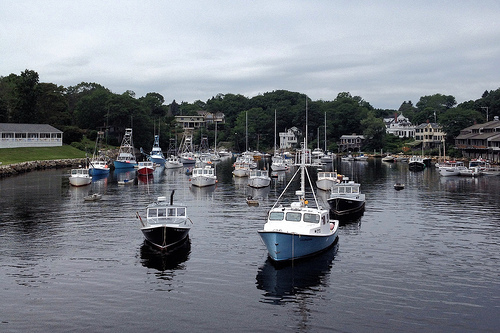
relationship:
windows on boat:
[267, 208, 323, 224] [236, 163, 348, 291]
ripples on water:
[332, 252, 459, 329] [0, 162, 499, 331]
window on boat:
[269, 211, 284, 221] [258, 95, 339, 264]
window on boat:
[283, 209, 302, 220] [258, 95, 339, 264]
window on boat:
[302, 212, 319, 223] [258, 95, 339, 264]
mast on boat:
[298, 96, 309, 206] [250, 102, 348, 254]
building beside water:
[455, 114, 497, 161] [0, 162, 499, 331]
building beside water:
[413, 118, 445, 149] [0, 162, 499, 331]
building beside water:
[380, 109, 417, 141] [0, 162, 499, 331]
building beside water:
[169, 103, 223, 129] [0, 162, 499, 331]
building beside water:
[2, 119, 63, 149] [0, 162, 499, 331]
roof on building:
[453, 105, 498, 157] [457, 116, 499, 159]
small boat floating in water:
[135, 176, 210, 264] [0, 162, 499, 331]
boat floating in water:
[135, 196, 196, 254] [0, 162, 499, 331]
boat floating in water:
[317, 176, 371, 221] [0, 162, 499, 331]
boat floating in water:
[181, 159, 216, 189] [0, 162, 499, 331]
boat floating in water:
[62, 158, 93, 190] [0, 162, 499, 331]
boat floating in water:
[430, 155, 482, 179] [0, 162, 499, 331]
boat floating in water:
[230, 147, 375, 294] [0, 162, 499, 331]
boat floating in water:
[128, 180, 212, 256] [0, 162, 499, 331]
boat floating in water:
[393, 177, 405, 189] [0, 162, 499, 331]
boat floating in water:
[136, 160, 153, 174] [0, 162, 499, 331]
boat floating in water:
[89, 191, 101, 200] [0, 162, 499, 331]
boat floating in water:
[245, 190, 260, 205] [0, 162, 499, 331]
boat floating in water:
[117, 177, 134, 186] [0, 162, 499, 331]